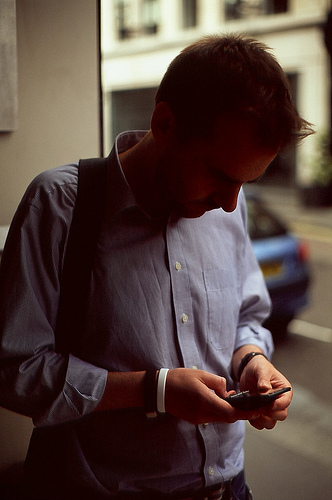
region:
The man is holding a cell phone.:
[207, 361, 309, 421]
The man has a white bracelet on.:
[158, 364, 178, 421]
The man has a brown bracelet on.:
[127, 362, 160, 428]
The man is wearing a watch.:
[223, 343, 276, 377]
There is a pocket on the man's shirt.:
[185, 252, 259, 353]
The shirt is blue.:
[87, 211, 295, 336]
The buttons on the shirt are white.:
[201, 460, 222, 486]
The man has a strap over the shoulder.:
[64, 147, 100, 344]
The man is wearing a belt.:
[184, 482, 241, 498]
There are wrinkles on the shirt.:
[113, 244, 189, 371]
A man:
[107, 51, 320, 385]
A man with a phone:
[125, 66, 292, 446]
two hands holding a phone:
[147, 360, 308, 440]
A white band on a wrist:
[132, 361, 179, 430]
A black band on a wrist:
[118, 357, 221, 436]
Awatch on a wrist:
[233, 340, 276, 383]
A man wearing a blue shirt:
[109, 72, 286, 347]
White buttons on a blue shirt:
[158, 249, 208, 357]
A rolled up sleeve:
[32, 335, 118, 431]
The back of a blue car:
[235, 202, 314, 333]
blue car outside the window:
[235, 190, 310, 351]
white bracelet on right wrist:
[157, 365, 171, 420]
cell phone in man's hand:
[223, 383, 291, 411]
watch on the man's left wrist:
[233, 347, 270, 384]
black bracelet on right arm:
[141, 356, 155, 419]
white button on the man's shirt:
[173, 256, 186, 273]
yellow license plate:
[254, 252, 291, 282]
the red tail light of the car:
[292, 236, 316, 265]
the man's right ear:
[145, 94, 181, 149]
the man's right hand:
[123, 363, 252, 430]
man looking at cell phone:
[123, 51, 310, 398]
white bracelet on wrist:
[154, 356, 173, 415]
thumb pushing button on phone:
[209, 371, 235, 398]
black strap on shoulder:
[60, 149, 110, 268]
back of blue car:
[258, 207, 328, 311]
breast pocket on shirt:
[201, 260, 247, 347]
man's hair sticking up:
[287, 119, 320, 147]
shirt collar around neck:
[100, 142, 136, 219]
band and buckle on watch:
[225, 351, 264, 367]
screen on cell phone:
[238, 387, 280, 396]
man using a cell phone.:
[37, 54, 313, 439]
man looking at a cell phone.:
[39, 53, 291, 448]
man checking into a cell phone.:
[52, 66, 308, 443]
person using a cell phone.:
[61, 100, 307, 437]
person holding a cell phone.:
[30, 18, 306, 440]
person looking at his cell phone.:
[37, 21, 308, 442]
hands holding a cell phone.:
[184, 350, 293, 442]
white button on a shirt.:
[172, 303, 185, 327]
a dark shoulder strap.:
[53, 133, 122, 353]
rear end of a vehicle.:
[236, 188, 314, 328]